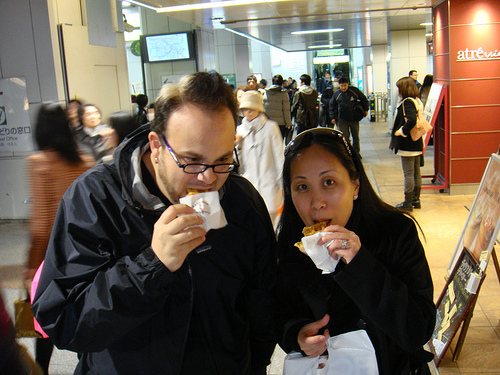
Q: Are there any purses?
A: Yes, there is a purse.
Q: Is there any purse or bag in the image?
A: Yes, there is a purse.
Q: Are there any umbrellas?
A: No, there are no umbrellas.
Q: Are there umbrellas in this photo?
A: No, there are no umbrellas.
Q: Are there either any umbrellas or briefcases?
A: No, there are no umbrellas or briefcases.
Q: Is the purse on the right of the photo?
A: Yes, the purse is on the right of the image.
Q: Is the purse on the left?
A: No, the purse is on the right of the image.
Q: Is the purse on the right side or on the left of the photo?
A: The purse is on the right of the image.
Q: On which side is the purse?
A: The purse is on the right of the image.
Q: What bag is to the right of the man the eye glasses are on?
A: The bag is a purse.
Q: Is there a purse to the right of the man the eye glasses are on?
A: Yes, there is a purse to the right of the man.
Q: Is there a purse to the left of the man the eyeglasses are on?
A: No, the purse is to the right of the man.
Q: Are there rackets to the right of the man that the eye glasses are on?
A: No, there is a purse to the right of the man.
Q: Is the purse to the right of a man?
A: Yes, the purse is to the right of a man.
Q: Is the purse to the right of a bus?
A: No, the purse is to the right of a man.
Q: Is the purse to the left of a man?
A: No, the purse is to the right of a man.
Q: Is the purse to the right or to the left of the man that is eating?
A: The purse is to the right of the man.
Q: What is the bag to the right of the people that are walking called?
A: The bag is a purse.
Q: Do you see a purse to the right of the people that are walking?
A: Yes, there is a purse to the right of the people.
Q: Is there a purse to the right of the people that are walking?
A: Yes, there is a purse to the right of the people.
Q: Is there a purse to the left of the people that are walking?
A: No, the purse is to the right of the people.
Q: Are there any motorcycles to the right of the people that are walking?
A: No, there is a purse to the right of the people.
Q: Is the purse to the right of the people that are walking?
A: Yes, the purse is to the right of the people.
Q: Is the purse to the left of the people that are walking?
A: No, the purse is to the right of the people.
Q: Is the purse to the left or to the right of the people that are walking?
A: The purse is to the right of the people.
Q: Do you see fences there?
A: No, there are no fences.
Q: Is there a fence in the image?
A: No, there are no fences.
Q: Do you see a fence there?
A: No, there are no fences.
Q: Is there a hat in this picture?
A: Yes, there is a hat.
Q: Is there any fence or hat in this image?
A: Yes, there is a hat.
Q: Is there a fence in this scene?
A: No, there are no fences.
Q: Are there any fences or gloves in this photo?
A: No, there are no fences or gloves.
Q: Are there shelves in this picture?
A: No, there are no shelves.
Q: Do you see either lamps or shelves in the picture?
A: No, there are no shelves or lamps.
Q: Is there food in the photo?
A: Yes, there is food.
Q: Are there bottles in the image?
A: No, there are no bottles.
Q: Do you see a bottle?
A: No, there are no bottles.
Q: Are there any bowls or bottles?
A: No, there are no bottles or bowls.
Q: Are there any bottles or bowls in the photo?
A: No, there are no bottles or bowls.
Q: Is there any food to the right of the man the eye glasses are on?
A: Yes, there is food to the right of the man.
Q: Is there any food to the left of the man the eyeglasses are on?
A: No, the food is to the right of the man.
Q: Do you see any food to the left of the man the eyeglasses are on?
A: No, the food is to the right of the man.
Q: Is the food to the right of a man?
A: Yes, the food is to the right of a man.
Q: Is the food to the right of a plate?
A: No, the food is to the right of a man.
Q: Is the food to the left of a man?
A: No, the food is to the right of a man.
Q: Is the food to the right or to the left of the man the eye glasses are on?
A: The food is to the right of the man.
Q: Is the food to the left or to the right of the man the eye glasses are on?
A: The food is to the right of the man.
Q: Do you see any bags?
A: Yes, there is a bag.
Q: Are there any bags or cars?
A: Yes, there is a bag.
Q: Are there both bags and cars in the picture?
A: No, there is a bag but no cars.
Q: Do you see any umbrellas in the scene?
A: No, there are no umbrellas.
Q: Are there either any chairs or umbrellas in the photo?
A: No, there are no umbrellas or chairs.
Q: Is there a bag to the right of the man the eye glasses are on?
A: Yes, there is a bag to the right of the man.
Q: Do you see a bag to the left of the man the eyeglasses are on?
A: No, the bag is to the right of the man.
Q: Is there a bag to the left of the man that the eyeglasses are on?
A: No, the bag is to the right of the man.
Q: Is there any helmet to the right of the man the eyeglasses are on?
A: No, there is a bag to the right of the man.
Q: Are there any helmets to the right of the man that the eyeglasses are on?
A: No, there is a bag to the right of the man.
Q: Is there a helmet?
A: No, there are no helmets.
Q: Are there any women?
A: Yes, there is a woman.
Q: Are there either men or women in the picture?
A: Yes, there is a woman.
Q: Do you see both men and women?
A: Yes, there are both a woman and a man.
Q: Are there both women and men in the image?
A: Yes, there are both a woman and a man.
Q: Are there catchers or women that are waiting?
A: Yes, the woman is waiting.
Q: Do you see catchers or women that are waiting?
A: Yes, the woman is waiting.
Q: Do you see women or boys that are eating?
A: Yes, the woman is eating.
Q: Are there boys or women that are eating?
A: Yes, the woman is eating.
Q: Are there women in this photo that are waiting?
A: Yes, there is a woman that is waiting.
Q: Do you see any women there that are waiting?
A: Yes, there is a woman that is waiting.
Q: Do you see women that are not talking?
A: Yes, there is a woman that is waiting .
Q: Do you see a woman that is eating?
A: Yes, there is a woman that is eating.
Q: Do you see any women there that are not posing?
A: Yes, there is a woman that is eating .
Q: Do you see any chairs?
A: No, there are no chairs.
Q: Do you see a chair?
A: No, there are no chairs.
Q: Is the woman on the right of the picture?
A: Yes, the woman is on the right of the image.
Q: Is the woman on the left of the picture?
A: No, the woman is on the right of the image.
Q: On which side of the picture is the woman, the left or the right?
A: The woman is on the right of the image.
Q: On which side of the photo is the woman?
A: The woman is on the right of the image.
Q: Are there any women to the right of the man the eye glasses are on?
A: Yes, there is a woman to the right of the man.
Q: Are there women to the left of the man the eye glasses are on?
A: No, the woman is to the right of the man.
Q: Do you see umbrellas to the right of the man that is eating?
A: No, there is a woman to the right of the man.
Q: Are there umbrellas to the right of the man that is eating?
A: No, there is a woman to the right of the man.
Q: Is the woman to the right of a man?
A: Yes, the woman is to the right of a man.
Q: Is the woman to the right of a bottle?
A: No, the woman is to the right of a man.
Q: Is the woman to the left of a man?
A: No, the woman is to the right of a man.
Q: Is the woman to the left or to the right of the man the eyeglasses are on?
A: The woman is to the right of the man.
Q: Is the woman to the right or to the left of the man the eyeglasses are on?
A: The woman is to the right of the man.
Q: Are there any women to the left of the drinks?
A: Yes, there is a woman to the left of the drinks.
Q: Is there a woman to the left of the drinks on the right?
A: Yes, there is a woman to the left of the drinks.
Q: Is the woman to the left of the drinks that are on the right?
A: Yes, the woman is to the left of the drinks.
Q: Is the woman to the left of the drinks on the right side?
A: Yes, the woman is to the left of the drinks.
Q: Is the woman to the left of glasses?
A: No, the woman is to the left of the drinks.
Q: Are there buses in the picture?
A: No, there are no buses.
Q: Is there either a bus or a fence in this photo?
A: No, there are no buses or fences.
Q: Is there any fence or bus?
A: No, there are no buses or fences.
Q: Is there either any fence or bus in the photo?
A: No, there are no fences or buses.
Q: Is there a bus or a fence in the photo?
A: No, there are no fences or buses.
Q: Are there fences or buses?
A: No, there are no fences or buses.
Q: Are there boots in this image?
A: Yes, there are boots.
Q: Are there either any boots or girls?
A: Yes, there are boots.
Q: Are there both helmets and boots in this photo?
A: No, there are boots but no helmets.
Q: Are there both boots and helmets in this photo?
A: No, there are boots but no helmets.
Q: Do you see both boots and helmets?
A: No, there are boots but no helmets.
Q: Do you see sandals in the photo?
A: No, there are no sandals.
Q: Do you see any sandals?
A: No, there are no sandals.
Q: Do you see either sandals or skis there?
A: No, there are no sandals or skis.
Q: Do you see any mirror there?
A: No, there are no mirrors.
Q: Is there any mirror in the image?
A: No, there are no mirrors.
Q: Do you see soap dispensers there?
A: No, there are no soap dispensers.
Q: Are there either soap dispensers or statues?
A: No, there are no soap dispensers or statues.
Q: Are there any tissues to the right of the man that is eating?
A: Yes, there is a tissue to the right of the man.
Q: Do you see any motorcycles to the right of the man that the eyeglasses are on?
A: No, there is a tissue to the right of the man.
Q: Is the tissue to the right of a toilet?
A: No, the tissue is to the right of a man.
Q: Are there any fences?
A: No, there are no fences.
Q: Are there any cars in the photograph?
A: No, there are no cars.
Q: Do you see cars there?
A: No, there are no cars.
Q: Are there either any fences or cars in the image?
A: No, there are no cars or fences.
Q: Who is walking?
A: The people are walking.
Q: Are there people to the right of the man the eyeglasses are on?
A: Yes, there are people to the right of the man.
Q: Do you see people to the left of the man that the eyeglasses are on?
A: No, the people are to the right of the man.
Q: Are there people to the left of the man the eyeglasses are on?
A: No, the people are to the right of the man.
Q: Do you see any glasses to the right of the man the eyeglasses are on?
A: No, there are people to the right of the man.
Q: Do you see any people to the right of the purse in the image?
A: No, the people are to the left of the purse.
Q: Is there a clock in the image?
A: No, there are no clocks.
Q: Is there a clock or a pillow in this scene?
A: No, there are no clocks or pillows.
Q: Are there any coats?
A: Yes, there is a coat.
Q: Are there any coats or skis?
A: Yes, there is a coat.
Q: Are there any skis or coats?
A: Yes, there is a coat.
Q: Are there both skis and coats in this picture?
A: No, there is a coat but no skis.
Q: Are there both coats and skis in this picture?
A: No, there is a coat but no skis.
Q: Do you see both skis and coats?
A: No, there is a coat but no skis.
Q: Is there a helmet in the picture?
A: No, there are no helmets.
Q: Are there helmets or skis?
A: No, there are no helmets or skis.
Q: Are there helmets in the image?
A: No, there are no helmets.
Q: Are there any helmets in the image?
A: No, there are no helmets.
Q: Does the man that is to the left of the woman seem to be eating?
A: Yes, the man is eating.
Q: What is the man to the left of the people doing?
A: The man is eating.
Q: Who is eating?
A: The man is eating.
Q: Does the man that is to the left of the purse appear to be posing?
A: No, the man is eating.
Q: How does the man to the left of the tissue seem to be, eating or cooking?
A: The man is eating.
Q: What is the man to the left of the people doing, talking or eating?
A: The man is eating.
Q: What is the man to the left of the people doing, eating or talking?
A: The man is eating.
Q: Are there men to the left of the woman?
A: Yes, there is a man to the left of the woman.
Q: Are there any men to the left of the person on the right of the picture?
A: Yes, there is a man to the left of the woman.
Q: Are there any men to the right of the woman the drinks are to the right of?
A: No, the man is to the left of the woman.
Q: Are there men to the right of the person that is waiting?
A: No, the man is to the left of the woman.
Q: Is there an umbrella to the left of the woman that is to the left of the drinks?
A: No, there is a man to the left of the woman.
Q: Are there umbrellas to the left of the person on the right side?
A: No, there is a man to the left of the woman.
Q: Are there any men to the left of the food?
A: Yes, there is a man to the left of the food.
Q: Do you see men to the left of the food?
A: Yes, there is a man to the left of the food.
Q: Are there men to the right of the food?
A: No, the man is to the left of the food.